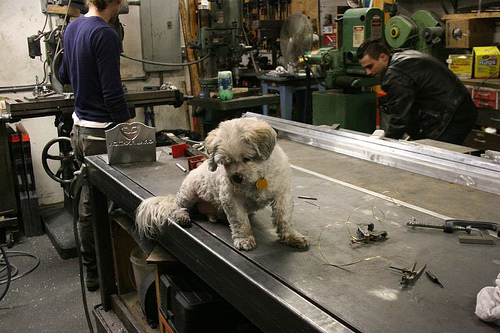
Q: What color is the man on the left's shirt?
A: Blue.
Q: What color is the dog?
A: White.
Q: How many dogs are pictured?
A: 1.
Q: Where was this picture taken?
A: At a grooming station.